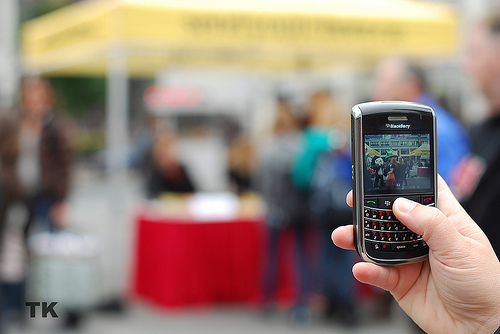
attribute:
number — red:
[371, 209, 376, 216]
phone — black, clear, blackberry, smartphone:
[351, 101, 438, 266]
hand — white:
[331, 172, 500, 333]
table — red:
[136, 210, 376, 308]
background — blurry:
[0, 0, 499, 333]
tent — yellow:
[18, 0, 465, 299]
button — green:
[363, 195, 380, 208]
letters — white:
[385, 121, 412, 130]